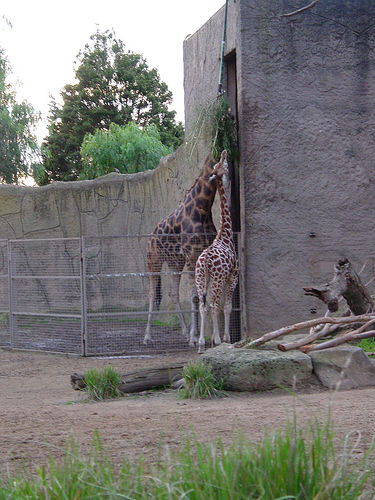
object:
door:
[214, 48, 243, 349]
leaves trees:
[77, 120, 168, 182]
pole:
[217, 14, 228, 92]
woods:
[233, 257, 372, 355]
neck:
[218, 185, 234, 243]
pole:
[75, 227, 91, 357]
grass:
[5, 426, 125, 500]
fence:
[0, 228, 244, 357]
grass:
[331, 436, 375, 499]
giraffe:
[138, 98, 236, 342]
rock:
[308, 343, 373, 391]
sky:
[1, 3, 182, 118]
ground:
[3, 346, 375, 498]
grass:
[178, 363, 225, 399]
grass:
[82, 366, 121, 400]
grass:
[161, 427, 326, 500]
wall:
[240, 2, 373, 336]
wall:
[3, 159, 231, 335]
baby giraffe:
[194, 147, 239, 353]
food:
[187, 97, 242, 162]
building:
[184, 0, 373, 353]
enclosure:
[3, 1, 371, 496]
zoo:
[0, 3, 372, 497]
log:
[68, 357, 192, 393]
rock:
[187, 344, 315, 392]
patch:
[1, 427, 106, 500]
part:
[149, 404, 189, 451]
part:
[246, 444, 286, 493]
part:
[220, 352, 244, 384]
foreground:
[2, 411, 370, 498]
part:
[246, 352, 278, 388]